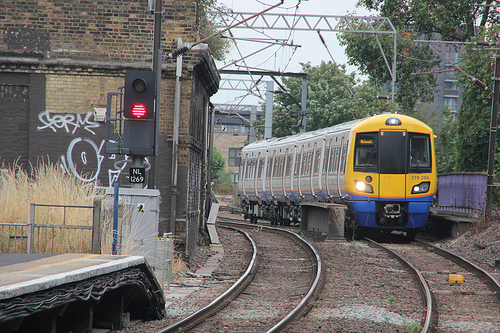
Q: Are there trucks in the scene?
A: No, there are no trucks.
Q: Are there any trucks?
A: No, there are no trucks.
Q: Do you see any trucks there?
A: No, there are no trucks.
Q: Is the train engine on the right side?
A: Yes, the train engine is on the right of the image.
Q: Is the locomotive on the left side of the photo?
A: No, the locomotive is on the right of the image.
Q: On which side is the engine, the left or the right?
A: The engine is on the right of the image.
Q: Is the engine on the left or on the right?
A: The engine is on the right of the image.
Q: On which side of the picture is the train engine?
A: The train engine is on the right of the image.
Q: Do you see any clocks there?
A: No, there are no clocks.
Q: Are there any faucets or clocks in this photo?
A: No, there are no clocks or faucets.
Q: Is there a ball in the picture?
A: No, there are no balls.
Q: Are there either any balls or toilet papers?
A: No, there are no balls or toilet papers.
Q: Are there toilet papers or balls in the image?
A: No, there are no balls or toilet papers.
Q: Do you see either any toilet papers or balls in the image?
A: No, there are no balls or toilet papers.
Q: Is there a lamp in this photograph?
A: No, there are no lamps.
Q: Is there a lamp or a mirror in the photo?
A: No, there are no lamps or mirrors.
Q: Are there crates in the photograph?
A: No, there are no crates.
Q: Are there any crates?
A: No, there are no crates.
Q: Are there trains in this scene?
A: Yes, there is a train.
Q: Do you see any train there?
A: Yes, there is a train.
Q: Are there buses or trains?
A: Yes, there is a train.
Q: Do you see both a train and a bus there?
A: No, there is a train but no buses.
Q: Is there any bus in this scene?
A: No, there are no buses.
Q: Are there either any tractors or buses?
A: No, there are no buses or tractors.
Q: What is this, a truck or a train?
A: This is a train.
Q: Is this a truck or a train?
A: This is a train.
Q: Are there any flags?
A: No, there are no flags.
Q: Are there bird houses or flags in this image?
A: No, there are no flags or bird houses.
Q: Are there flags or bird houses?
A: No, there are no flags or bird houses.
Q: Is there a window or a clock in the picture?
A: Yes, there are windows.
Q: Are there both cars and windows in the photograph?
A: No, there are windows but no cars.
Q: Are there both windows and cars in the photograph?
A: No, there are windows but no cars.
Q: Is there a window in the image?
A: Yes, there is a window.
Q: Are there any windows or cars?
A: Yes, there is a window.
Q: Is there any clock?
A: No, there are no clocks.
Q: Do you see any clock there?
A: No, there are no clocks.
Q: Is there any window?
A: Yes, there is a window.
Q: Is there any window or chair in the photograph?
A: Yes, there is a window.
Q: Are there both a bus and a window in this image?
A: No, there is a window but no buses.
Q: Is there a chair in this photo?
A: No, there are no chairs.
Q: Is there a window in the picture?
A: Yes, there are windows.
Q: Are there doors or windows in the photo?
A: Yes, there are windows.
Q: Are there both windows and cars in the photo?
A: No, there are windows but no cars.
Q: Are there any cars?
A: No, there are no cars.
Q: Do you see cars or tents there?
A: No, there are no cars or tents.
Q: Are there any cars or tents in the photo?
A: No, there are no cars or tents.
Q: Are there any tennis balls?
A: No, there are no tennis balls.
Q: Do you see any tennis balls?
A: No, there are no tennis balls.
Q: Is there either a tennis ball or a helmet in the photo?
A: No, there are no tennis balls or helmets.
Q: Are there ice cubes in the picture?
A: No, there are no ice cubes.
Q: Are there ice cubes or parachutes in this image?
A: No, there are no ice cubes or parachutes.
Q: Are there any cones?
A: No, there are no cones.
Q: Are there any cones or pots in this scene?
A: No, there are no cones or pots.